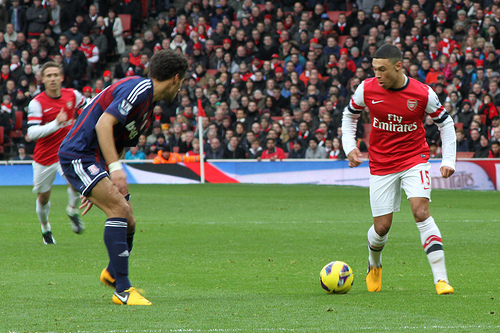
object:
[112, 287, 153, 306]
cleats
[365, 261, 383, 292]
cleats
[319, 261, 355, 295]
yellow ball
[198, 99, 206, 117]
red flag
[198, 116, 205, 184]
white pole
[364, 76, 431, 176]
red jersey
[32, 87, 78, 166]
red jersey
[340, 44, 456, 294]
guy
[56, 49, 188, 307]
guy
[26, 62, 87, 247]
guy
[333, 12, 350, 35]
guy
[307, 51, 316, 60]
guy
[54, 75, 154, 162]
jersey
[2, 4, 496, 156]
fans